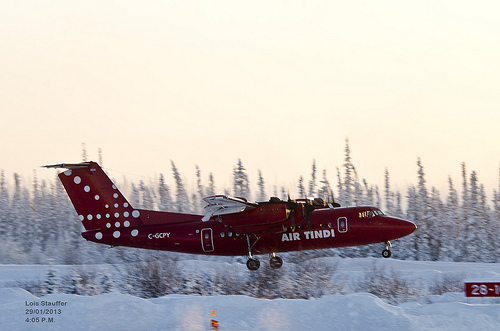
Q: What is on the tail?
A: White spots.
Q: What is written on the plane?
A: Air tindi.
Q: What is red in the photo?
A: A plane.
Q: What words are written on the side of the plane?
A: Air Tindi.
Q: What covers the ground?
A: Snow.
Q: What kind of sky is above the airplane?
A: Clear.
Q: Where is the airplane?
A: In the air.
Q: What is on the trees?
A: Snow.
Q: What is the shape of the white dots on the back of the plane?
A: Circle.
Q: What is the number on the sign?
A: 28.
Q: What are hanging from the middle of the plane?
A: Wheels.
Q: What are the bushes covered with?
A: Snow.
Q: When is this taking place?
A: Daytime.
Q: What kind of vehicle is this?
A: Airplane.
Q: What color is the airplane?
A: Red and white.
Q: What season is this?
A: Winter.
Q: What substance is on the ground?
A: Snow.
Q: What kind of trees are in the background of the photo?
A: Evergreen trees.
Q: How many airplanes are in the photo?
A: One.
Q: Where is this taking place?
A: On a tarmac.